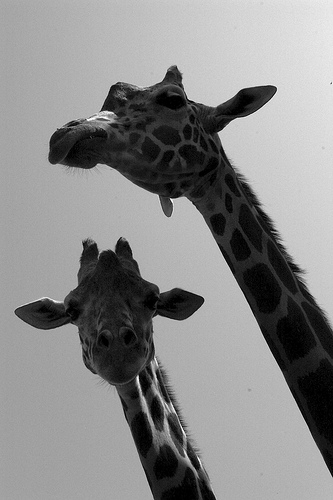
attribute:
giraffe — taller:
[24, 66, 330, 455]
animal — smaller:
[43, 245, 193, 397]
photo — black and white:
[1, 1, 330, 493]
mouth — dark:
[39, 130, 106, 173]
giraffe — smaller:
[9, 229, 225, 496]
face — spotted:
[41, 59, 301, 217]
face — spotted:
[9, 234, 211, 391]